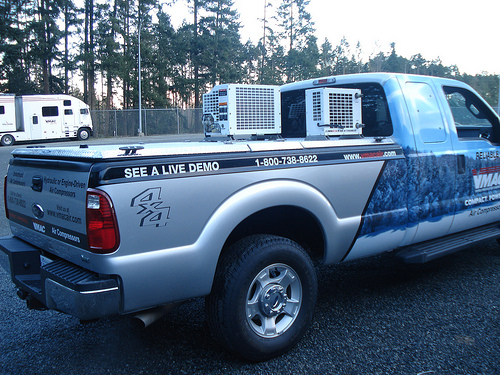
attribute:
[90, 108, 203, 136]
fence — small, metal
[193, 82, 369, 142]
machines — white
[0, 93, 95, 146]
recreational vehicle — white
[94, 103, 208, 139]
fence — chain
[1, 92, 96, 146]
rv — white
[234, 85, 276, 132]
holes — small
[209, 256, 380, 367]
tire — black, chrome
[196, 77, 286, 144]
vent — white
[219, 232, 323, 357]
tire — black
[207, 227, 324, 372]
black tire — rubber